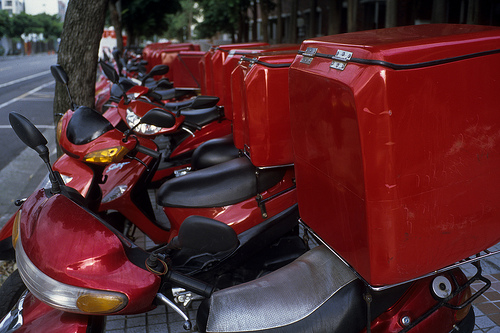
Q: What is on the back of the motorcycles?
A: Boxes.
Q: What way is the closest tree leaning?
A: To the right.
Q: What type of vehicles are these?
A: Scooters.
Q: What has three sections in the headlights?
A: The vehicle.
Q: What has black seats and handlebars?
A: All the mopeds.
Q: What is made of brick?
A: Sidewalk.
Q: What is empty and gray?
A: The street.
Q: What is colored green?
A: The leaves.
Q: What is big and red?
A: Luggage box.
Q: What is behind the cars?
A: Trees.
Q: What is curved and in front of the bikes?
A: Curved tree.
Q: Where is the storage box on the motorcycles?
A: On the back.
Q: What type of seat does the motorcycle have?
A: A banana type seat.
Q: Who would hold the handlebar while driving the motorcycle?
A: The biker.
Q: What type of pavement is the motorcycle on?
A: Tiles.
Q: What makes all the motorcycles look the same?
A: They are all red.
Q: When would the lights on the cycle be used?
A: At night.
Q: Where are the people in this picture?
A: In the back left.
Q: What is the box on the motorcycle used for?
A: Storage.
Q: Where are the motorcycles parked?
A: On the sidewalk.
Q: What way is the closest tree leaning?
A: Right.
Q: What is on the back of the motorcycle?
A: A cargo carrier.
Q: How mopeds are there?
A: 13.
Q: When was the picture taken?
A: Day time.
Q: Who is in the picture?
A: No one.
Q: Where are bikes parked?
A: Sidewalk.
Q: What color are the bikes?
A: Red.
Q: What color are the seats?
A: Black.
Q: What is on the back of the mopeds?
A: Warmers.